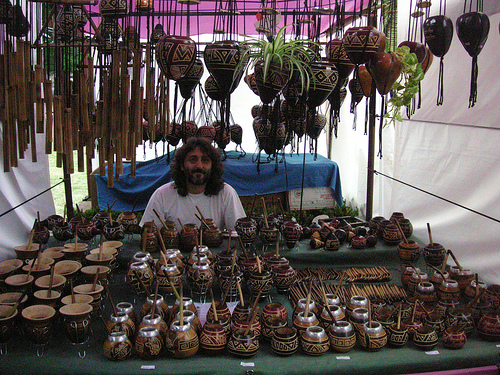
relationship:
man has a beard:
[139, 138, 246, 228] [183, 165, 211, 186]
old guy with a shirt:
[166, 129, 227, 202] [146, 183, 249, 234]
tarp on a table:
[93, 141, 343, 209] [238, 150, 344, 208]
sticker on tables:
[331, 352, 356, 362] [283, 347, 441, 372]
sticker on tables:
[421, 342, 444, 359] [283, 347, 441, 372]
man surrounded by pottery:
[139, 138, 246, 228] [1, 210, 498, 354]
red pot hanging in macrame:
[362, 52, 402, 94] [149, 2, 469, 117]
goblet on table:
[59, 300, 93, 354] [2, 345, 494, 371]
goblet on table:
[18, 302, 56, 358] [2, 345, 494, 371]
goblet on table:
[79, 261, 111, 305] [2, 345, 494, 371]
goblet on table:
[0, 269, 36, 301] [2, 345, 494, 371]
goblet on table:
[86, 245, 116, 286] [2, 345, 494, 371]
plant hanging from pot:
[219, 22, 326, 109] [255, 60, 295, 103]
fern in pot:
[230, 21, 327, 102] [252, 55, 300, 105]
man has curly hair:
[139, 138, 246, 228] [157, 130, 230, 190]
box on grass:
[285, 187, 337, 209] [238, 192, 360, 216]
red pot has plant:
[362, 52, 402, 94] [383, 41, 424, 125]